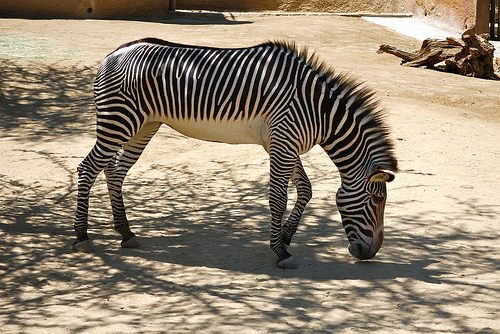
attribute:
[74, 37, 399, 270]
zebra — here, standing, black, sniffing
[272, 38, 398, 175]
mane — standing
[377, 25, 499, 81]
wood — here